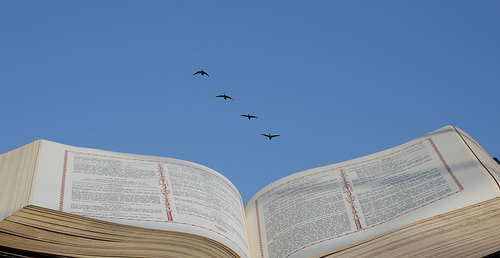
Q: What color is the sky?
A: Blue.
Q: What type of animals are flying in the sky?
A: Birds.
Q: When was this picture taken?
A: During the Day.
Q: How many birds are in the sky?
A: Four.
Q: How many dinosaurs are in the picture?
A: Zero.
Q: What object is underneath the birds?
A: A book.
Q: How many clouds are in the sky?
A: Zero.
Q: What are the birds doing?
A: Flying.